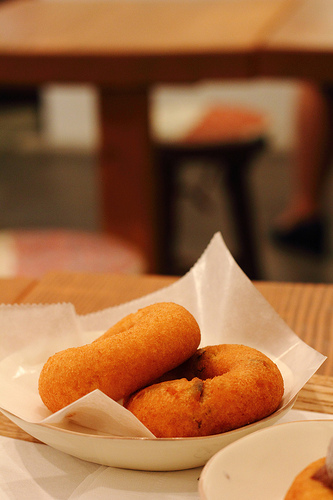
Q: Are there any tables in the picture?
A: Yes, there is a table.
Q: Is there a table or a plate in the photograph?
A: Yes, there is a table.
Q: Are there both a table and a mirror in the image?
A: No, there is a table but no mirrors.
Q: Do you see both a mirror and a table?
A: No, there is a table but no mirrors.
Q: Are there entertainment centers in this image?
A: No, there are no entertainment centers.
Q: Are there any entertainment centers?
A: No, there are no entertainment centers.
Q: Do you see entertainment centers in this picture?
A: No, there are no entertainment centers.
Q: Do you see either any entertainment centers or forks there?
A: No, there are no entertainment centers or forks.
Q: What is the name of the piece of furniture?
A: The piece of furniture is a table.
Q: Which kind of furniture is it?
A: The piece of furniture is a table.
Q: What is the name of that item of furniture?
A: This is a table.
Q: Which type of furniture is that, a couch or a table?
A: This is a table.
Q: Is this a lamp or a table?
A: This is a table.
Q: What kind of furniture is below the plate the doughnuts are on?
A: The piece of furniture is a table.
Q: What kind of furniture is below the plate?
A: The piece of furniture is a table.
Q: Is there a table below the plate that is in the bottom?
A: Yes, there is a table below the plate.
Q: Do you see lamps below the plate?
A: No, there is a table below the plate.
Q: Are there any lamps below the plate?
A: No, there is a table below the plate.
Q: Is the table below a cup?
A: No, the table is below the plate.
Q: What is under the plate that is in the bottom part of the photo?
A: The table is under the plate.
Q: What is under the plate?
A: The table is under the plate.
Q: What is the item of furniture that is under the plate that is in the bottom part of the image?
A: The piece of furniture is a table.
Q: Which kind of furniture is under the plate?
A: The piece of furniture is a table.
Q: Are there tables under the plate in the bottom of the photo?
A: Yes, there is a table under the plate.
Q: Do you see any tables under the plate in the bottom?
A: Yes, there is a table under the plate.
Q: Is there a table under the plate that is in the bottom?
A: Yes, there is a table under the plate.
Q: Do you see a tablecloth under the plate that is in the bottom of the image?
A: No, there is a table under the plate.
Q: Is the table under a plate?
A: Yes, the table is under a plate.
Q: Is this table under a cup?
A: No, the table is under a plate.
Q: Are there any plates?
A: Yes, there is a plate.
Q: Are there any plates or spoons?
A: Yes, there is a plate.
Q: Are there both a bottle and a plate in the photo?
A: No, there is a plate but no bottles.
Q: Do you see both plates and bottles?
A: No, there is a plate but no bottles.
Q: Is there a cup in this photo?
A: No, there are no cups.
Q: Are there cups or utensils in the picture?
A: No, there are no cups or utensils.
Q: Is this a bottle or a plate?
A: This is a plate.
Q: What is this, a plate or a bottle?
A: This is a plate.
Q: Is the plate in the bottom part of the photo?
A: Yes, the plate is in the bottom of the image.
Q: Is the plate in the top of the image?
A: No, the plate is in the bottom of the image.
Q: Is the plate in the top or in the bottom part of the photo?
A: The plate is in the bottom of the image.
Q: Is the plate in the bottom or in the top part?
A: The plate is in the bottom of the image.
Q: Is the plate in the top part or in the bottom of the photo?
A: The plate is in the bottom of the image.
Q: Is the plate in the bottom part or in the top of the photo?
A: The plate is in the bottom of the image.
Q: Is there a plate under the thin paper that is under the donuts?
A: Yes, there is a plate under the paper.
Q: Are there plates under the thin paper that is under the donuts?
A: Yes, there is a plate under the paper.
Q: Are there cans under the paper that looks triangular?
A: No, there is a plate under the paper.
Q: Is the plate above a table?
A: Yes, the plate is above a table.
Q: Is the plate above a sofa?
A: No, the plate is above a table.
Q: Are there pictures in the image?
A: No, there are no pictures.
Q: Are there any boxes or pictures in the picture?
A: No, there are no pictures or boxes.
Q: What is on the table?
A: The paper is on the table.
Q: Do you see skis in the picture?
A: No, there are no skis.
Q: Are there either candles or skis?
A: No, there are no skis or candles.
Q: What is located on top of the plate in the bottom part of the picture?
A: The paper is on top of the plate.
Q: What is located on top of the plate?
A: The paper is on top of the plate.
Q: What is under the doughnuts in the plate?
A: The paper is under the doughnuts.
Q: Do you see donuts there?
A: Yes, there are donuts.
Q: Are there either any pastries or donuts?
A: Yes, there are donuts.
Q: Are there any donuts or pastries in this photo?
A: Yes, there are donuts.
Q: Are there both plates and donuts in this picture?
A: Yes, there are both donuts and a plate.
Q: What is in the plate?
A: The doughnuts are in the plate.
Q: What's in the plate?
A: The doughnuts are in the plate.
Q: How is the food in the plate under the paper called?
A: The food is donuts.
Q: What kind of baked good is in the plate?
A: The food is donuts.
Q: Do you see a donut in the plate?
A: Yes, there are donuts in the plate.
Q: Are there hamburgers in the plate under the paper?
A: No, there are donuts in the plate.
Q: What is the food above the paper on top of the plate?
A: The food is donuts.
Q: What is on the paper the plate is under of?
A: The donuts are on the paper.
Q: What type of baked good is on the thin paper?
A: The food is donuts.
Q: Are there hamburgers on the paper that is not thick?
A: No, there are donuts on the paper.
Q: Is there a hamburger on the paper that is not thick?
A: No, there are donuts on the paper.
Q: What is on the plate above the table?
A: The doughnuts are on the plate.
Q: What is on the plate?
A: The doughnuts are on the plate.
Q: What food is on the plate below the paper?
A: The food is donuts.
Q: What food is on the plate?
A: The food is donuts.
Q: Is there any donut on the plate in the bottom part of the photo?
A: Yes, there are donuts on the plate.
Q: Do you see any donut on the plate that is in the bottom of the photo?
A: Yes, there are donuts on the plate.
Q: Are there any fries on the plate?
A: No, there are donuts on the plate.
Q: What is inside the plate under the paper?
A: The doughnuts are inside the plate.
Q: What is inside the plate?
A: The doughnuts are inside the plate.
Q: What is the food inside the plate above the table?
A: The food is donuts.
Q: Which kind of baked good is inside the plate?
A: The food is donuts.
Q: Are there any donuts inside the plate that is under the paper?
A: Yes, there are donuts inside the plate.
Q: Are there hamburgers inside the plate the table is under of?
A: No, there are donuts inside the plate.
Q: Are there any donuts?
A: Yes, there is a donut.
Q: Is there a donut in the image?
A: Yes, there is a donut.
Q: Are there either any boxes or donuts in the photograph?
A: Yes, there is a donut.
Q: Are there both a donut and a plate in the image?
A: Yes, there are both a donut and a plate.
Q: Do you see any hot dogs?
A: No, there are no hot dogs.